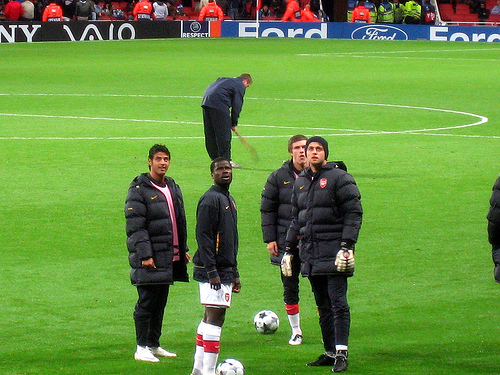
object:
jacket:
[123, 172, 191, 286]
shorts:
[198, 279, 230, 310]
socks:
[284, 303, 301, 336]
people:
[348, 0, 371, 25]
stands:
[0, 0, 499, 43]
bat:
[229, 130, 262, 163]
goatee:
[218, 172, 233, 189]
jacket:
[283, 160, 365, 277]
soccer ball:
[215, 356, 246, 375]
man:
[122, 142, 195, 363]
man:
[259, 133, 324, 347]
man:
[279, 135, 364, 374]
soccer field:
[0, 41, 499, 373]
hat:
[299, 134, 330, 160]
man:
[184, 156, 241, 374]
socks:
[200, 320, 223, 375]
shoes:
[329, 348, 349, 374]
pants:
[306, 278, 351, 353]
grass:
[1, 40, 500, 375]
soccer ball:
[251, 309, 279, 335]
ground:
[0, 41, 499, 375]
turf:
[0, 36, 497, 374]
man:
[197, 72, 256, 164]